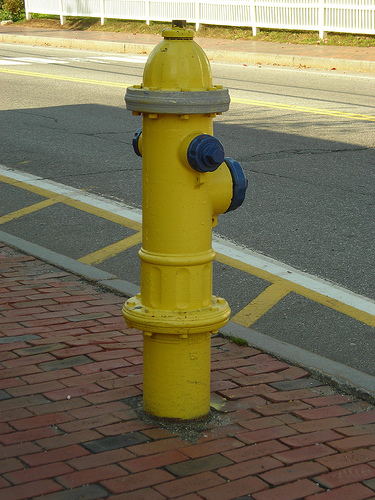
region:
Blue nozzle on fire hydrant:
[183, 138, 241, 182]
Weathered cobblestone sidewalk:
[43, 407, 187, 497]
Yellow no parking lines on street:
[231, 274, 327, 346]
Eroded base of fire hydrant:
[137, 332, 239, 456]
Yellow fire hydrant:
[117, 73, 197, 312]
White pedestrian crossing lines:
[9, 43, 126, 82]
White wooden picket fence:
[109, 4, 314, 40]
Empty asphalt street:
[5, 57, 106, 166]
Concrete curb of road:
[13, 231, 120, 300]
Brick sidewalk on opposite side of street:
[60, 26, 130, 52]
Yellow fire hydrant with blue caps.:
[114, 20, 237, 430]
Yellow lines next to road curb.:
[0, 161, 373, 401]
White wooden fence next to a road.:
[16, 0, 374, 52]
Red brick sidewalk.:
[1, 233, 372, 496]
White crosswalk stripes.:
[1, 33, 152, 90]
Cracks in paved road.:
[19, 112, 369, 184]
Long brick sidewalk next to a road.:
[1, 24, 374, 76]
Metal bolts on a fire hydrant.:
[125, 108, 229, 121]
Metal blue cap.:
[185, 129, 228, 175]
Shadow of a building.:
[7, 99, 138, 200]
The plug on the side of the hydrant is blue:
[184, 144, 237, 181]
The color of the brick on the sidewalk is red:
[276, 413, 301, 443]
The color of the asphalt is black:
[335, 327, 356, 356]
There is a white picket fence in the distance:
[329, 8, 350, 28]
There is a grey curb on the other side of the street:
[69, 41, 93, 64]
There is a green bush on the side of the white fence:
[10, 5, 16, 20]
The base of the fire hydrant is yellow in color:
[128, 268, 246, 423]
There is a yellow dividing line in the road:
[313, 101, 326, 130]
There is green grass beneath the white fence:
[336, 36, 350, 45]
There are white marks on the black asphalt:
[35, 58, 51, 69]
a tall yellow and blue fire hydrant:
[121, 12, 249, 415]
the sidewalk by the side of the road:
[2, 240, 372, 498]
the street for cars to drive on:
[2, 38, 373, 361]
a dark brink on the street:
[162, 453, 238, 476]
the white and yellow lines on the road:
[0, 166, 373, 392]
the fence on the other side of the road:
[24, 0, 372, 41]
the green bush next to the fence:
[1, 1, 22, 21]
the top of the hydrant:
[160, 18, 193, 38]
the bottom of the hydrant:
[141, 332, 213, 423]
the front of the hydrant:
[216, 158, 249, 208]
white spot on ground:
[50, 392, 101, 428]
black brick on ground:
[76, 424, 158, 451]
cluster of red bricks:
[240, 417, 345, 471]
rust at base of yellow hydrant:
[150, 398, 225, 436]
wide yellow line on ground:
[241, 286, 305, 321]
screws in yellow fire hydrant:
[135, 311, 202, 349]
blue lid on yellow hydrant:
[172, 134, 240, 172]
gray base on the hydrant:
[98, 76, 275, 130]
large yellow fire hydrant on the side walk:
[136, 33, 236, 417]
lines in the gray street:
[258, 135, 353, 192]